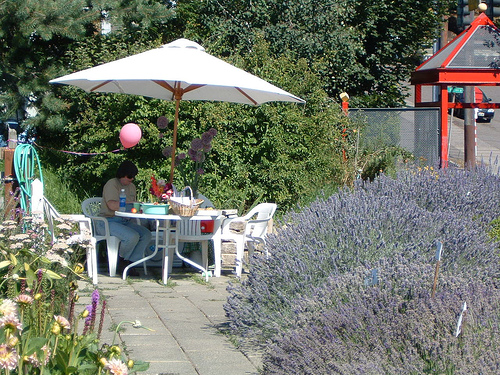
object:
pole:
[169, 101, 180, 185]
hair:
[116, 161, 138, 180]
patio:
[0, 36, 500, 375]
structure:
[413, 2, 497, 174]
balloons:
[156, 116, 169, 129]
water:
[119, 192, 127, 212]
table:
[113, 208, 239, 286]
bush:
[221, 130, 500, 375]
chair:
[27, 177, 99, 285]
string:
[29, 140, 123, 155]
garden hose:
[12, 143, 52, 240]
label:
[121, 198, 126, 202]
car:
[440, 84, 493, 122]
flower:
[87, 291, 99, 337]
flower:
[81, 307, 92, 337]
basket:
[169, 186, 204, 217]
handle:
[180, 186, 194, 206]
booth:
[411, 14, 500, 169]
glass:
[450, 86, 500, 166]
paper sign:
[434, 241, 443, 260]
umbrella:
[49, 36, 304, 107]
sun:
[205, 19, 300, 66]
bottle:
[119, 189, 127, 212]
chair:
[219, 203, 277, 279]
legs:
[103, 223, 139, 261]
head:
[118, 161, 139, 186]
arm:
[104, 186, 136, 207]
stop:
[330, 88, 443, 169]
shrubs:
[0, 262, 121, 375]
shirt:
[99, 177, 136, 216]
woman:
[93, 160, 153, 276]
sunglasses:
[126, 173, 136, 179]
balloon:
[119, 123, 141, 149]